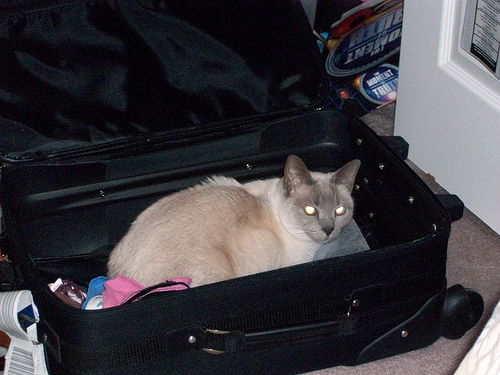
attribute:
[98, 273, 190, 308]
panties — pink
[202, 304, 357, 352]
handle — black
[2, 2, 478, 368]
bag — here, black, open, rolling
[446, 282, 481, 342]
wheel — here, black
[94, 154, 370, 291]
cat — white, here, beige, looking, awake, grey, tan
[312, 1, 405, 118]
box — game, moment of truth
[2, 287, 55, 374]
tag — airport id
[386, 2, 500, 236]
door — here, white, painted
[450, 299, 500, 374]
mattress — in corner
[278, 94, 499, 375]
floor — here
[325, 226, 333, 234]
nose — black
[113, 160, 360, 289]
fur — light brown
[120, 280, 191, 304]
lining — black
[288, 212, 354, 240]
whiskers — gray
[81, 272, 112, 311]
clothing — blue, white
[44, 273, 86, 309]
clothing — brown, white